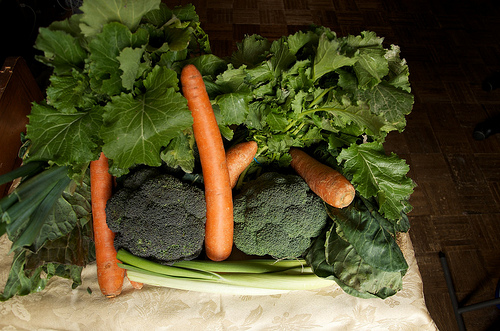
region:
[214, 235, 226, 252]
part of a carrot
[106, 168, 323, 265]
Broccoli separated by a carrot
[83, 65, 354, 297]
Four orange carrots in various places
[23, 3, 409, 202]
Two big bunches of lettuce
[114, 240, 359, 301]
Long green stems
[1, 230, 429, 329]
Ivory pillow with leafy design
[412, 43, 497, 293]
Brown cross pattern in squares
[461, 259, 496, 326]
Shadow cast by black stand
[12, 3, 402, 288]
Mound of fresh vegetables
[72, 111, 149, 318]
This is a carrot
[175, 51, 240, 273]
This is a carrot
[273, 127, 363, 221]
This is a carrot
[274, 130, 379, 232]
This is a carrot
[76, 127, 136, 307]
This is a carrot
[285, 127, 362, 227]
This is a carrot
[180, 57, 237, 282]
This is a carrot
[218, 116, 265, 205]
This is a carrot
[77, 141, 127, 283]
this is a carrot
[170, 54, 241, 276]
this is a carrot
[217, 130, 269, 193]
this is a carrot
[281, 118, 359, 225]
this is a carrot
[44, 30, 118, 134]
this is a vegetable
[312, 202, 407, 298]
this is a vegetable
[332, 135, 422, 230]
this is a vegetable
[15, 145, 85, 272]
this is a vegetable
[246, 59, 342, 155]
this is a vegetable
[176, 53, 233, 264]
Orange veggie on a table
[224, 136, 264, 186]
Orange veggie on a table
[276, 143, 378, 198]
Orange veggie on a table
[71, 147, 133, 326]
Orange veggie on a table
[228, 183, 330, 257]
Green veggie on a table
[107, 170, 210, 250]
Green veggie on a table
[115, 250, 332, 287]
Green veggie on a table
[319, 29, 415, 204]
Green leafy veggie on a table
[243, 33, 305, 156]
Green leafy veggie on a table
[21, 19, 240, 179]
Green leafy veggie on a table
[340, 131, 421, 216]
green leaf vegetable in the pile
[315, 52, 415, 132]
green leaf vegetable in the pile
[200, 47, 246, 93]
green leaf vegetable in the pile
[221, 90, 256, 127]
green leaf vegetable in the pile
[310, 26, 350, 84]
green leaf vegetable in the pile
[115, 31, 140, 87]
green leaf vegetable in the pile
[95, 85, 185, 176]
green leaf vegetable in the pile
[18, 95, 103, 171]
green leaf vegetable in the pile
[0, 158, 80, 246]
green leaf vegetable in the pile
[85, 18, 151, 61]
green leaf vegetable in the pile